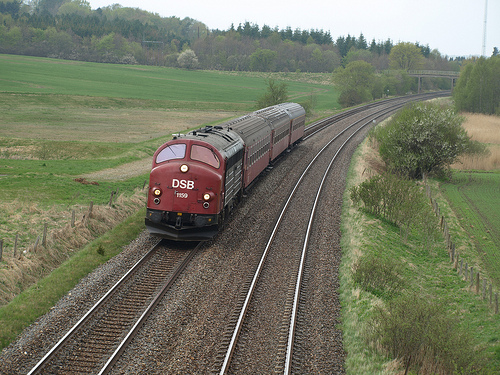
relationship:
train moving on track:
[137, 99, 310, 253] [31, 235, 195, 375]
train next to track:
[137, 99, 310, 253] [213, 119, 389, 371]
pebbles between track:
[186, 279, 227, 319] [31, 235, 195, 375]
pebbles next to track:
[311, 282, 338, 364] [213, 119, 389, 371]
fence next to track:
[8, 184, 133, 278] [31, 235, 195, 375]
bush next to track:
[350, 246, 403, 300] [213, 119, 389, 371]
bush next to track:
[346, 164, 423, 236] [213, 119, 389, 371]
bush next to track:
[368, 296, 482, 374] [213, 119, 389, 371]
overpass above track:
[407, 64, 462, 98] [215, 95, 432, 375]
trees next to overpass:
[449, 54, 498, 119] [407, 64, 462, 98]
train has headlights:
[137, 99, 310, 253] [148, 183, 213, 213]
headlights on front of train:
[148, 183, 213, 213] [137, 99, 310, 253]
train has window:
[137, 99, 310, 253] [156, 143, 187, 164]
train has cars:
[137, 99, 310, 253] [244, 93, 311, 195]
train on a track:
[137, 99, 310, 253] [31, 235, 195, 375]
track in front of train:
[31, 235, 195, 375] [137, 99, 310, 253]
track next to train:
[213, 119, 389, 371] [137, 99, 310, 253]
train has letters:
[137, 99, 310, 253] [170, 176, 197, 193]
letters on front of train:
[170, 176, 197, 193] [137, 99, 310, 253]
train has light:
[137, 99, 310, 253] [198, 190, 215, 214]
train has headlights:
[137, 99, 310, 253] [154, 190, 160, 194]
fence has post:
[8, 184, 133, 278] [66, 208, 78, 231]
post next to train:
[66, 208, 78, 231] [137, 99, 310, 253]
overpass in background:
[407, 64, 462, 98] [263, 1, 496, 128]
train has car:
[137, 99, 310, 253] [282, 97, 310, 148]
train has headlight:
[137, 99, 310, 253] [176, 163, 193, 175]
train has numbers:
[137, 99, 310, 253] [173, 188, 193, 204]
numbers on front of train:
[173, 188, 193, 204] [137, 99, 310, 253]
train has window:
[137, 99, 310, 253] [154, 136, 187, 167]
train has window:
[137, 99, 310, 253] [190, 140, 226, 172]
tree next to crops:
[373, 98, 467, 181] [439, 170, 498, 270]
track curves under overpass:
[215, 95, 432, 375] [407, 64, 462, 98]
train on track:
[137, 99, 310, 253] [31, 235, 195, 375]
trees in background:
[231, 20, 372, 51] [263, 1, 496, 128]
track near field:
[31, 235, 195, 375] [13, 82, 145, 202]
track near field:
[213, 119, 389, 371] [13, 82, 145, 202]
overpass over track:
[407, 64, 462, 98] [215, 95, 432, 375]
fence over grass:
[8, 184, 133, 278] [41, 224, 109, 263]